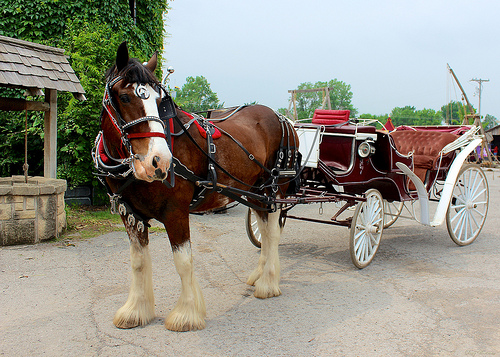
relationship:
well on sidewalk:
[3, 32, 83, 249] [3, 252, 500, 355]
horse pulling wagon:
[81, 38, 298, 330] [250, 101, 487, 266]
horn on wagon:
[355, 141, 376, 163] [250, 101, 487, 266]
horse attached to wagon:
[81, 38, 298, 330] [250, 101, 487, 266]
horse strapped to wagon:
[81, 38, 298, 330] [250, 101, 487, 266]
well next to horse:
[3, 32, 83, 249] [81, 38, 298, 330]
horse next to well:
[81, 38, 298, 330] [3, 32, 83, 249]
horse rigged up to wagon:
[81, 38, 298, 330] [250, 101, 487, 266]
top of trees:
[175, 75, 353, 107] [180, 80, 474, 125]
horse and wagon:
[81, 38, 298, 330] [250, 101, 487, 266]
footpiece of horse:
[391, 137, 488, 228] [81, 38, 298, 330]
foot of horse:
[160, 290, 214, 331] [81, 38, 298, 330]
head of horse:
[97, 43, 173, 185] [81, 38, 298, 330]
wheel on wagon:
[343, 187, 389, 271] [250, 101, 487, 266]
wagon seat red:
[250, 101, 487, 266] [403, 134, 425, 149]